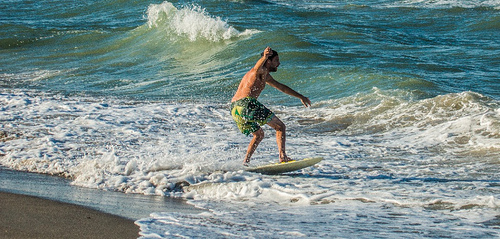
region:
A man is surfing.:
[203, 30, 350, 182]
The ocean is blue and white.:
[0, 0, 497, 202]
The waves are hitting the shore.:
[0, 78, 499, 233]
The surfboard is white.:
[228, 156, 328, 173]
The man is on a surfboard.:
[225, 45, 320, 177]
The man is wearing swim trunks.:
[228, 93, 277, 135]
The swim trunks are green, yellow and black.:
[226, 92, 281, 138]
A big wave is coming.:
[111, 2, 373, 55]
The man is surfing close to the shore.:
[0, 0, 498, 236]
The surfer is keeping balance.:
[230, 41, 320, 183]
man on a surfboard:
[214, 37, 353, 178]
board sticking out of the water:
[240, 150, 332, 176]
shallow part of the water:
[1, 79, 498, 237]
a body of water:
[1, 0, 498, 236]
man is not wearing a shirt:
[219, 35, 322, 159]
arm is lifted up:
[252, 43, 272, 80]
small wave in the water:
[135, 2, 260, 49]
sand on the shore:
[1, 190, 148, 237]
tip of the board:
[309, 151, 329, 164]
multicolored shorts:
[222, 95, 278, 142]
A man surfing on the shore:
[198, 41, 331, 181]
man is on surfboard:
[206, 28, 314, 176]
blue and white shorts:
[240, 95, 261, 147]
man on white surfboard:
[243, 157, 323, 180]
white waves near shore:
[229, 169, 411, 235]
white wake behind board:
[169, 128, 256, 175]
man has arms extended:
[205, 74, 315, 114]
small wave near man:
[345, 61, 495, 188]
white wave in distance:
[84, 1, 291, 63]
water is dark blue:
[306, 18, 433, 85]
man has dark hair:
[252, 39, 299, 74]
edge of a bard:
[279, 138, 310, 164]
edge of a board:
[271, 140, 301, 174]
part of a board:
[290, 146, 317, 168]